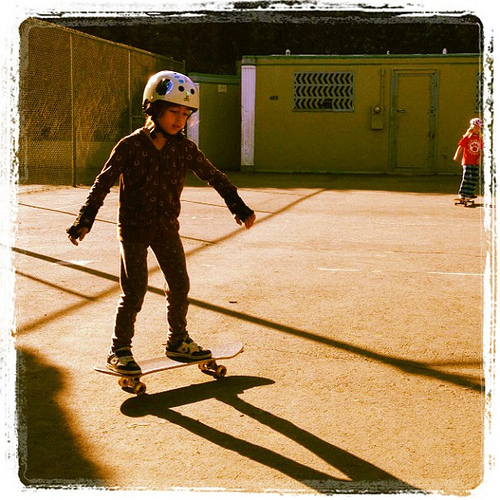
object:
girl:
[66, 69, 260, 376]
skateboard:
[93, 342, 248, 396]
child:
[453, 117, 486, 207]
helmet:
[143, 68, 203, 113]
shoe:
[165, 335, 214, 364]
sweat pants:
[110, 231, 192, 351]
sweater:
[72, 129, 241, 241]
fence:
[18, 25, 188, 186]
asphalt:
[13, 174, 482, 490]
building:
[186, 54, 485, 179]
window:
[294, 73, 354, 113]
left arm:
[183, 140, 245, 212]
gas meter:
[369, 67, 385, 131]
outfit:
[453, 133, 486, 197]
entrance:
[390, 69, 436, 176]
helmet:
[467, 118, 485, 129]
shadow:
[120, 370, 421, 499]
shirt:
[459, 133, 485, 164]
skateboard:
[454, 198, 477, 207]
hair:
[462, 116, 484, 141]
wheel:
[216, 364, 228, 379]